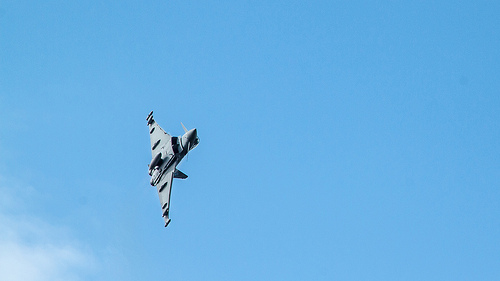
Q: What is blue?
A: Sky.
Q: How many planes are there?
A: One.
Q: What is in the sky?
A: Plane.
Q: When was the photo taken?
A: Daytime.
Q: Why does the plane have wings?
A: To fly.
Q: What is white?
A: Clouds.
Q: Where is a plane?
A: In the sky.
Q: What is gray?
A: The plane.